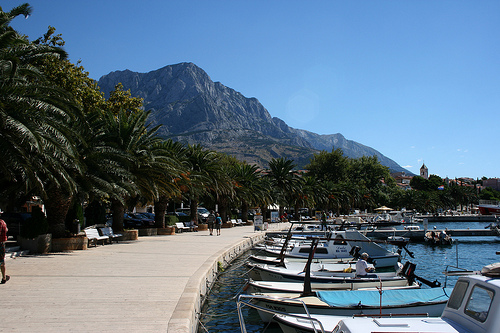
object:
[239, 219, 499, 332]
row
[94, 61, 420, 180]
moutain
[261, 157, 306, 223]
tree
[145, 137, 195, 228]
tree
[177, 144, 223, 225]
tree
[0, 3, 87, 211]
tree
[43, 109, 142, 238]
tree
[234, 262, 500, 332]
boat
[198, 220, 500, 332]
water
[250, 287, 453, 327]
boat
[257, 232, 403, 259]
boat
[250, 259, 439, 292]
boat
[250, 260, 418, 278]
boat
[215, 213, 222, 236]
person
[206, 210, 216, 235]
person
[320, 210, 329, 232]
person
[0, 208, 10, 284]
person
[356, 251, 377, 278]
person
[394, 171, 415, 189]
building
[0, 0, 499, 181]
sky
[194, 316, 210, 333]
rope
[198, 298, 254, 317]
rope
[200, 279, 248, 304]
rope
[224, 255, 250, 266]
rope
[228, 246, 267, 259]
rope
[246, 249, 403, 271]
boat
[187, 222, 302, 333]
wall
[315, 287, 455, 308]
cover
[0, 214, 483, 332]
sidewalk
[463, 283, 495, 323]
front window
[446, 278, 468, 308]
front window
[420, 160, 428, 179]
steeple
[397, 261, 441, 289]
motor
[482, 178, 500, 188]
building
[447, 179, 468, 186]
building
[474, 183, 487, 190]
building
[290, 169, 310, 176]
building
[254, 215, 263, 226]
sign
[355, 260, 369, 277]
shirt